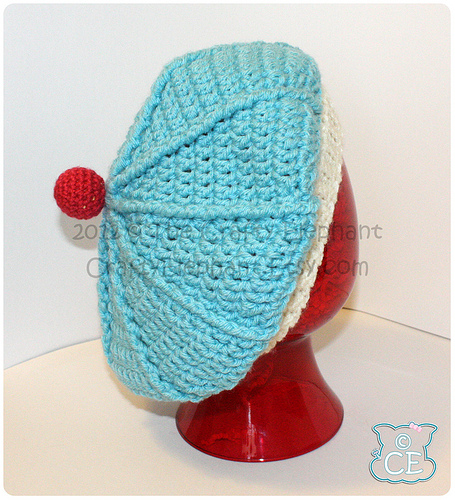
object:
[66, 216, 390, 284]
watermark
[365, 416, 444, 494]
cecopyright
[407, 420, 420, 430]
bow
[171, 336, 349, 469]
base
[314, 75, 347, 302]
trim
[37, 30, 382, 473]
maniquin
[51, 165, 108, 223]
ball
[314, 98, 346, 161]
ground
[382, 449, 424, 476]
ce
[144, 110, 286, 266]
thread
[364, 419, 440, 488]
logo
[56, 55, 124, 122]
wall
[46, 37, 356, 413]
hat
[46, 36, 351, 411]
cover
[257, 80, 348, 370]
white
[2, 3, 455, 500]
background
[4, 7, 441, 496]
photo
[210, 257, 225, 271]
hole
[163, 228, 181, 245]
hole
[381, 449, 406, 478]
letter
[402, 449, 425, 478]
letter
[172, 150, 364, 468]
mannequin